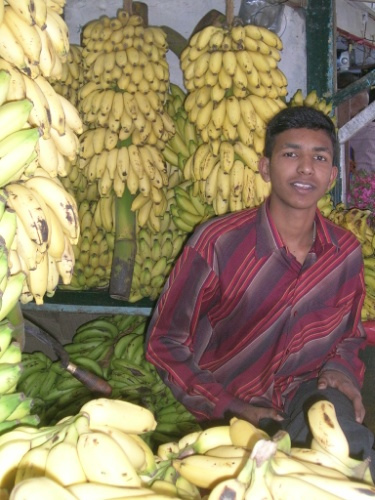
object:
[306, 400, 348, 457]
banana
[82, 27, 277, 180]
fruit bunches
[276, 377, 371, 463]
cloth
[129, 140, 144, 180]
banana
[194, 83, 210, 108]
banana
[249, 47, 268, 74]
banana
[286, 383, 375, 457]
pants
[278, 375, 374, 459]
black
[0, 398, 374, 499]
bananas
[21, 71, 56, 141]
banana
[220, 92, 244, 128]
banana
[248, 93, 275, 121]
banana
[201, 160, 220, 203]
banana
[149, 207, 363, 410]
shirt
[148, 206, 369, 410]
stripes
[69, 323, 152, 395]
green bananas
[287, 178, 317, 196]
mouth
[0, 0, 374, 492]
building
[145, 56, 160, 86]
banana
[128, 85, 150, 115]
banana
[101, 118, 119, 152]
banana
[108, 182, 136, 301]
pole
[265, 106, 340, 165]
hair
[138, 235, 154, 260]
banana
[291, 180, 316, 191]
teeth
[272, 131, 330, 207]
face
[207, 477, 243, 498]
ripe banana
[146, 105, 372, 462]
man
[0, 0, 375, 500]
wall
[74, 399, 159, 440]
banana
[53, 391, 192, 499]
ripe banana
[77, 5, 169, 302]
bananas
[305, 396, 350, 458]
fruit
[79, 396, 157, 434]
fruit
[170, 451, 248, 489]
fruit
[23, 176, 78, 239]
fruit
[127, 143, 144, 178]
fruit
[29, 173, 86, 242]
banana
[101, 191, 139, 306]
trunk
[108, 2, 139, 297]
beam